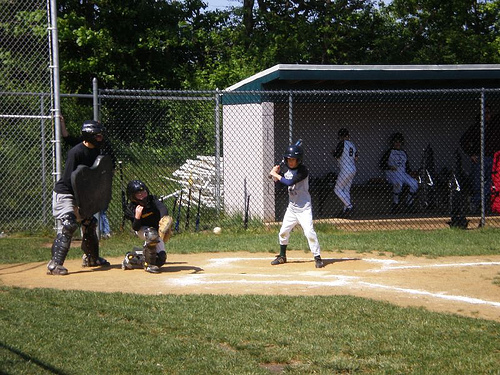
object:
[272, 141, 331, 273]
boy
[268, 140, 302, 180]
bat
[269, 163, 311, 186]
right shoulder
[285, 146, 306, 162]
helmet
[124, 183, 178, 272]
catcher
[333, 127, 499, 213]
baseball players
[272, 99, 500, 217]
rest area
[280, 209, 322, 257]
pants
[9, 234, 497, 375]
field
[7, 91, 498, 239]
fence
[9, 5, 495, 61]
trees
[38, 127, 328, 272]
boys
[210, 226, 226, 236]
baseball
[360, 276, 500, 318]
lines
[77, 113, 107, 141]
helmet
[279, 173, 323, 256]
players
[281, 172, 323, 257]
white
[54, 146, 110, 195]
players dress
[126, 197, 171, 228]
black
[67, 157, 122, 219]
shield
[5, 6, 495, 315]
picture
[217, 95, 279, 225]
shed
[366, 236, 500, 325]
dirt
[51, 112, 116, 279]
umpire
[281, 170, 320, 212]
shirt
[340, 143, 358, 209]
shirt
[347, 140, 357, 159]
number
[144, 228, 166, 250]
skinpads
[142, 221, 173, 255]
protection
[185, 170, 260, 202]
air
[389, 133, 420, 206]
boy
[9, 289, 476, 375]
grass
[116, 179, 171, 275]
boy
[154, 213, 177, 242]
glove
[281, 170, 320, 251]
team shirt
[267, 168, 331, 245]
uniform